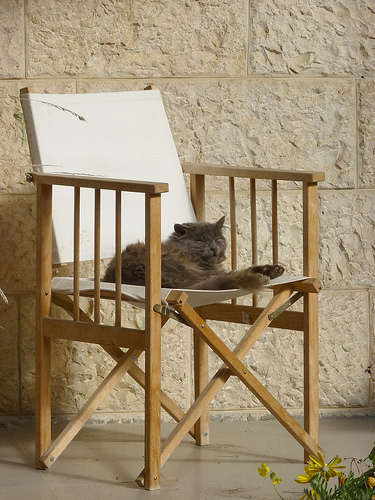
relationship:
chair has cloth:
[14, 81, 331, 498] [28, 87, 193, 232]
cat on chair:
[102, 215, 281, 288] [14, 81, 331, 498]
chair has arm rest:
[14, 81, 331, 498] [20, 167, 171, 193]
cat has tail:
[102, 215, 281, 288] [190, 270, 272, 294]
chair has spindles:
[14, 81, 331, 498] [63, 184, 133, 330]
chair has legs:
[14, 81, 331, 498] [34, 313, 329, 484]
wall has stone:
[5, 7, 374, 415] [256, 6, 374, 85]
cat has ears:
[102, 215, 281, 288] [166, 214, 229, 235]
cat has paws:
[102, 215, 281, 288] [255, 264, 290, 284]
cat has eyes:
[102, 215, 281, 288] [190, 232, 225, 244]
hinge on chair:
[148, 307, 190, 331] [14, 81, 331, 498]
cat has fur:
[102, 215, 281, 288] [123, 245, 144, 283]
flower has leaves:
[304, 447, 342, 492] [310, 481, 363, 499]